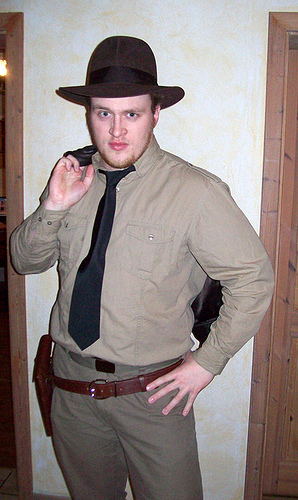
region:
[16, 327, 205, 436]
man wearing a holster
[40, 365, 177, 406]
man wearing a brown belt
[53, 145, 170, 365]
man wearing a tie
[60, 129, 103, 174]
man holding a jacket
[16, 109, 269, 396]
man wearing a light colored shirt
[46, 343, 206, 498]
man wearing grey pants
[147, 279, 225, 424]
man with hand at hip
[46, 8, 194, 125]
man wearing a cowboy hat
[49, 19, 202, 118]
man wearing a hat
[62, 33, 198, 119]
man wearing a brown hat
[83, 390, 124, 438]
this is a fly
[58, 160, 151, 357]
this is a tie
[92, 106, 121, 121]
this is an eye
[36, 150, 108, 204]
this is a hand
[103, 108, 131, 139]
this is a nose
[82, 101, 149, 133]
these are the eyes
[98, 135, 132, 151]
these are the lips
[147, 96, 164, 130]
this is an ear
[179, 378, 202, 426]
this is a pinkie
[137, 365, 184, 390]
this is a pointer finger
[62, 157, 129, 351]
the tie is black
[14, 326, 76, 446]
a brown leather gun holder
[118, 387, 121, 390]
the hole in the belt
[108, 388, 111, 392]
the hole in the belt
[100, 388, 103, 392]
the hole in the belt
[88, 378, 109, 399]
the buckle on the belt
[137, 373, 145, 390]
the loop on the belt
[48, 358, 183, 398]
the belt on the man's waist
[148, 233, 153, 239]
the button on the man's pocket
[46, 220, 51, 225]
the button on the man's cuff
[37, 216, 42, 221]
the button on the man's cuff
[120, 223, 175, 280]
the pocket on the man's shirt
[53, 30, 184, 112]
a man wearing a brown hat with a black band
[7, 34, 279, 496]
the man appears to be dressed as a sherif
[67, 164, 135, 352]
the man wears a tie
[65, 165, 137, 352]
the neck tie is black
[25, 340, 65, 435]
the man has a gun holster on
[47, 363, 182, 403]
the man wears a holster belt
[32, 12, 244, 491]
the wall behind the man is white and yellow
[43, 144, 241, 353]
the man threw a jacket over his shoulder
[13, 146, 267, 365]
the man wears a dark khaki shirt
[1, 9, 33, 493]
part of the door frame